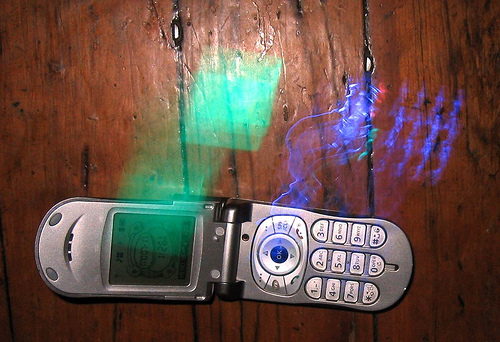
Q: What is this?
A: Phone.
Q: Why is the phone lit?
A: Its on.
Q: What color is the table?
A: Brown.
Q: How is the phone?
A: On.